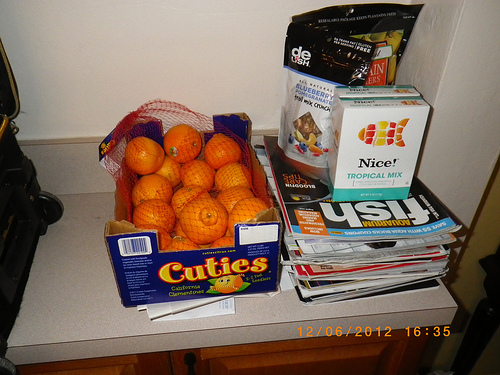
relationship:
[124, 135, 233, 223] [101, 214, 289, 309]
oranges in box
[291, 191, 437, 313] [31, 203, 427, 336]
magazines on counter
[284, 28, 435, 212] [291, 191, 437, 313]
nuts on magazines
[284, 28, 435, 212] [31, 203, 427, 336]
nuts on counter